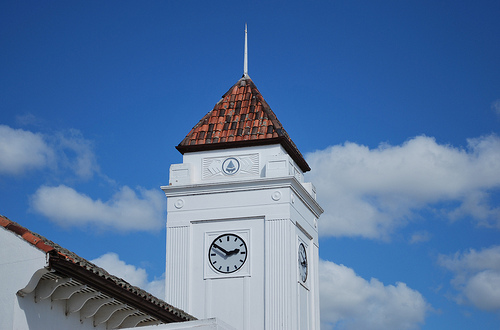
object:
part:
[334, 142, 370, 167]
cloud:
[298, 132, 500, 248]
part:
[370, 40, 420, 109]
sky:
[0, 0, 499, 330]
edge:
[288, 182, 293, 330]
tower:
[158, 25, 321, 329]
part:
[292, 243, 303, 268]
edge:
[370, 208, 403, 248]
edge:
[0, 209, 199, 321]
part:
[397, 252, 433, 292]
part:
[348, 156, 406, 186]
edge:
[239, 235, 249, 270]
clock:
[207, 231, 249, 277]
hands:
[214, 242, 229, 255]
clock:
[298, 243, 311, 285]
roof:
[177, 74, 316, 175]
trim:
[160, 173, 296, 199]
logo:
[221, 157, 241, 177]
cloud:
[27, 181, 167, 239]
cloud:
[2, 123, 58, 182]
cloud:
[319, 258, 432, 329]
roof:
[0, 217, 199, 323]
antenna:
[240, 22, 249, 78]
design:
[200, 156, 222, 181]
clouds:
[435, 243, 499, 312]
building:
[0, 22, 327, 329]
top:
[240, 18, 256, 86]